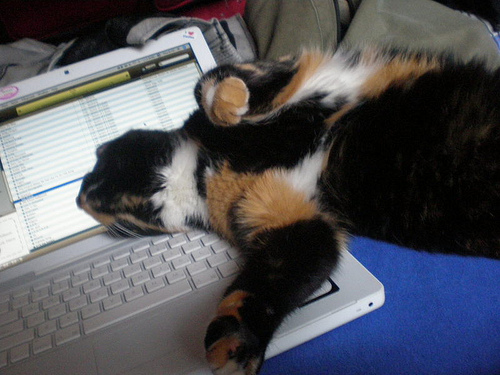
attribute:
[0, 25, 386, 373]
laptop — open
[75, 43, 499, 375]
cat — hairy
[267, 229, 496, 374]
surface — blue